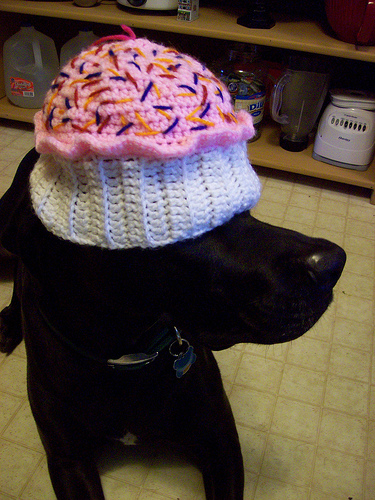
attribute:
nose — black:
[306, 244, 346, 291]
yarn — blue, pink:
[139, 79, 156, 103]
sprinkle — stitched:
[150, 101, 175, 111]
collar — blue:
[37, 304, 199, 376]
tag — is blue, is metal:
[169, 324, 197, 378]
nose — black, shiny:
[293, 235, 345, 292]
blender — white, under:
[311, 83, 373, 173]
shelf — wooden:
[0, 1, 374, 202]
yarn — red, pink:
[30, 28, 261, 250]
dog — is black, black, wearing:
[1, 149, 347, 494]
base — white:
[302, 99, 370, 176]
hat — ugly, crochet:
[67, 38, 244, 223]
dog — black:
[10, 107, 350, 499]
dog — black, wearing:
[55, 238, 344, 391]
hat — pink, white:
[36, 50, 258, 245]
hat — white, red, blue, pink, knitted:
[24, 18, 266, 255]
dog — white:
[1, 24, 346, 499]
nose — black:
[305, 236, 346, 287]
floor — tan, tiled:
[1, 124, 374, 497]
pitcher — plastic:
[265, 55, 332, 153]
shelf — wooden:
[4, 2, 373, 62]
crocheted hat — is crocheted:
[27, 17, 258, 161]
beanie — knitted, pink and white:
[13, 37, 269, 223]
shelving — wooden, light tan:
[0, 7, 372, 199]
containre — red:
[291, 8, 358, 39]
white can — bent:
[322, 91, 372, 174]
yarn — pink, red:
[32, 34, 266, 160]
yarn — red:
[122, 68, 142, 95]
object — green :
[268, 69, 323, 148]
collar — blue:
[101, 326, 198, 381]